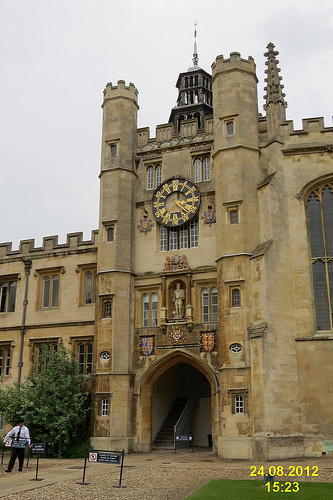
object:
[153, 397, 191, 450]
stairs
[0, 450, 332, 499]
pavement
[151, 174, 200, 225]
clock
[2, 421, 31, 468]
man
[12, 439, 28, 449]
sign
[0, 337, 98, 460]
tree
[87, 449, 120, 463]
sign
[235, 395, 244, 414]
window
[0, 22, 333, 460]
building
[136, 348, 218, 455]
entrance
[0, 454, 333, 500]
floor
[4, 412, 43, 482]
man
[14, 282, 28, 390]
pipe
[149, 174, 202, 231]
numbers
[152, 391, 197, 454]
staircase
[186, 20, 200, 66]
metal spire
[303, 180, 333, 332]
window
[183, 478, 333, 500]
grass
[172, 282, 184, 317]
statue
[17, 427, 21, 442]
tie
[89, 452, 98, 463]
forbidden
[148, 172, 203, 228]
roman numerals